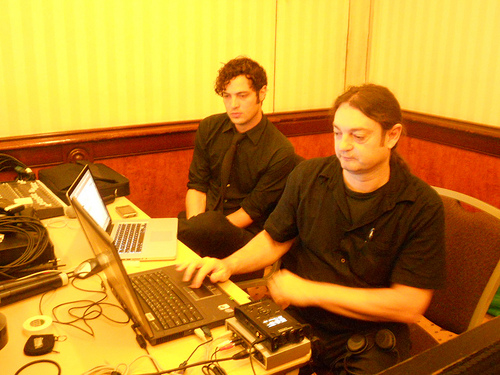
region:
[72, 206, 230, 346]
laptop on a desk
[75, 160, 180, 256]
laptop on a desk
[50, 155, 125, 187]
laptop bag on a desk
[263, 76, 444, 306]
man looking at a laptop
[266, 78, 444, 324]
man wearing a black shirt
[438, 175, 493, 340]
chair next to a desk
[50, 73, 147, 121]
yellow wall with stripes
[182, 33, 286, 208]
man wearing a black shirt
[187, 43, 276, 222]
man wearing a black tie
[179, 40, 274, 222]
man sitting at a desk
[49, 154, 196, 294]
the laptop is on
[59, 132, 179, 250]
the laptop is on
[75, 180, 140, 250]
the laptop is on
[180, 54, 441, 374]
the men look at the computer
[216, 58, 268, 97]
the man has curly hair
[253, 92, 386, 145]
the men have side burns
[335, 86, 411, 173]
the man has long hair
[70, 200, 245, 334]
the laptop is black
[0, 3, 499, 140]
the wall has stripes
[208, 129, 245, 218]
the man has a black ties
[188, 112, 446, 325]
the men wear black shirts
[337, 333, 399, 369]
the man has headphones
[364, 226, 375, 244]
the man has pen in his pocket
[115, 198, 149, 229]
a cellphone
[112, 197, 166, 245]
a cellphone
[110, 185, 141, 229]
a cellphone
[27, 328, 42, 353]
coin purse is black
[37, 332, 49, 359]
coin purse is black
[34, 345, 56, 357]
coin purse is black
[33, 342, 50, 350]
coin purse is black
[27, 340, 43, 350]
coin purse is black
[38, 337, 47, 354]
coin purse is black